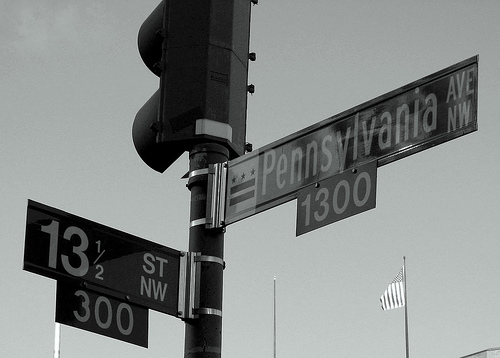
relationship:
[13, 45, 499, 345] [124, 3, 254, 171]
signs under light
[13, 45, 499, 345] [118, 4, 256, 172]
signs under lights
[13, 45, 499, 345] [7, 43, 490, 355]
signs facing different directions